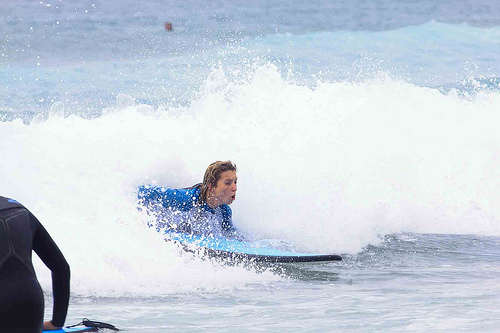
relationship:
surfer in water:
[135, 160, 241, 246] [1, 11, 481, 323]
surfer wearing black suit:
[135, 160, 245, 246] [1, 195, 74, 332]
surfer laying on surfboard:
[135, 160, 241, 246] [169, 228, 345, 267]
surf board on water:
[162, 236, 349, 264] [1, 11, 481, 323]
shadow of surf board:
[247, 261, 344, 283] [162, 236, 349, 264]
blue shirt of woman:
[137, 185, 235, 232] [138, 161, 246, 243]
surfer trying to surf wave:
[135, 160, 241, 246] [0, 48, 498, 300]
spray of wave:
[242, 58, 499, 201] [0, 48, 498, 300]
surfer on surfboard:
[135, 160, 241, 246] [165, 234, 341, 267]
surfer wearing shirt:
[135, 160, 241, 246] [131, 174, 206, 221]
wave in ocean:
[0, 48, 498, 300] [5, 2, 496, 323]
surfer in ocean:
[135, 160, 241, 246] [77, 205, 493, 331]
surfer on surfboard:
[135, 160, 241, 246] [130, 146, 341, 267]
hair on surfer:
[197, 160, 238, 199] [135, 160, 241, 246]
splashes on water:
[198, 34, 288, 85] [1, 11, 481, 323]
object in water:
[149, 12, 179, 36] [1, 11, 481, 323]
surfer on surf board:
[135, 160, 241, 246] [162, 232, 344, 266]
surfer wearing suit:
[135, 160, 241, 246] [137, 182, 234, 234]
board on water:
[32, 312, 112, 331] [116, 294, 467, 331]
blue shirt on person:
[137, 185, 235, 232] [139, 160, 239, 242]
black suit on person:
[1, 195, 72, 332] [139, 160, 239, 242]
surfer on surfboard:
[135, 160, 241, 246] [170, 218, 356, 288]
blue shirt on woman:
[137, 185, 235, 232] [110, 152, 250, 246]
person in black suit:
[0, 192, 71, 329] [1, 195, 72, 332]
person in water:
[161, 17, 178, 36] [1, 11, 481, 323]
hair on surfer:
[195, 157, 238, 206] [77, 157, 259, 254]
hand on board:
[43, 314, 54, 326] [32, 318, 119, 331]